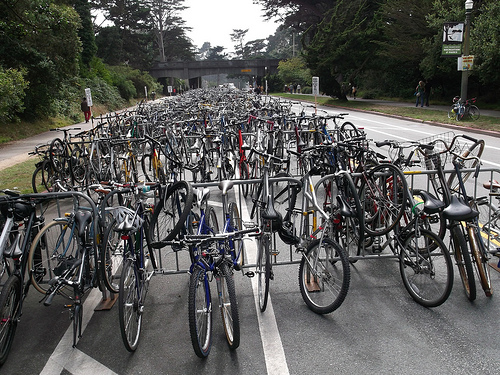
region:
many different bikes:
[77, 43, 345, 321]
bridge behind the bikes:
[163, 47, 272, 94]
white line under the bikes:
[246, 322, 292, 367]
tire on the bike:
[275, 230, 360, 320]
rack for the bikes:
[226, 172, 301, 257]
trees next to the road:
[317, 10, 394, 80]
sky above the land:
[212, 0, 232, 25]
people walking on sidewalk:
[395, 65, 441, 121]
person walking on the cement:
[65, 85, 102, 127]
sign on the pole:
[415, 17, 470, 80]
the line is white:
[267, 355, 277, 367]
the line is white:
[274, 348, 286, 371]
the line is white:
[256, 352, 280, 370]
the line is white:
[260, 334, 280, 362]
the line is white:
[271, 354, 280, 363]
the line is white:
[264, 341, 281, 359]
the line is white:
[262, 337, 277, 353]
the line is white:
[269, 337, 276, 347]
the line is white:
[80, 357, 90, 374]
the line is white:
[87, 363, 91, 368]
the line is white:
[74, 351, 84, 372]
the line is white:
[67, 353, 87, 372]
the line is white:
[84, 366, 91, 371]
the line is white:
[71, 363, 81, 370]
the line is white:
[87, 370, 89, 373]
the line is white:
[72, 348, 87, 368]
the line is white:
[82, 363, 99, 373]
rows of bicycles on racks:
[0, 84, 499, 355]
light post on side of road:
[460, 2, 471, 113]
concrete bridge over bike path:
[143, 58, 292, 93]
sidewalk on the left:
[3, 92, 178, 159]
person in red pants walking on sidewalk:
[78, 95, 92, 125]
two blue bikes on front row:
[194, 187, 243, 350]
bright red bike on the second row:
[235, 126, 247, 185]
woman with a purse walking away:
[414, 81, 425, 108]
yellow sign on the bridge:
[241, 68, 251, 73]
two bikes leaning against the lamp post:
[447, 96, 480, 123]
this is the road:
[294, 324, 461, 365]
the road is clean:
[301, 329, 481, 374]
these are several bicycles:
[16, 102, 474, 361]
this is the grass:
[401, 109, 440, 116]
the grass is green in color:
[417, 109, 439, 117]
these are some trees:
[335, 0, 490, 91]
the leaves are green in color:
[346, 11, 374, 32]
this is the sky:
[203, 3, 225, 25]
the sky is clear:
[206, 9, 247, 31]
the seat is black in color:
[263, 200, 277, 217]